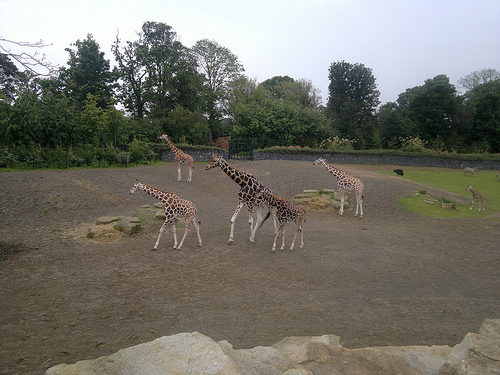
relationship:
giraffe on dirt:
[126, 167, 211, 277] [148, 244, 209, 271]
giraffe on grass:
[126, 167, 211, 277] [127, 129, 162, 156]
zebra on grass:
[464, 181, 490, 209] [127, 129, 162, 156]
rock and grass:
[175, 333, 215, 368] [127, 129, 162, 156]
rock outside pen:
[175, 333, 215, 368] [0, 150, 499, 372]